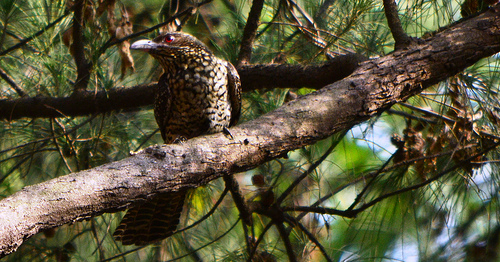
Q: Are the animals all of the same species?
A: Yes, all the animals are birds.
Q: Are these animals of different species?
A: No, all the animals are birds.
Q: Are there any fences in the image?
A: No, there are no fences.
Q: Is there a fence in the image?
A: No, there are no fences.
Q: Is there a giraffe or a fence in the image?
A: No, there are no fences or giraffes.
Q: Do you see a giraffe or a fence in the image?
A: No, there are no fences or giraffes.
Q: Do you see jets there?
A: No, there are no jets.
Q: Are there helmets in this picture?
A: No, there are no helmets.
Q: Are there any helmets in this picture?
A: No, there are no helmets.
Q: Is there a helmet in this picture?
A: No, there are no helmets.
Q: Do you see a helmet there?
A: No, there are no helmets.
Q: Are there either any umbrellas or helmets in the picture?
A: No, there are no helmets or umbrellas.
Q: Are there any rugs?
A: No, there are no rugs.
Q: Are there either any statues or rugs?
A: No, there are no rugs or statues.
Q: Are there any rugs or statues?
A: No, there are no rugs or statues.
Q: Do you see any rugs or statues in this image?
A: No, there are no rugs or statues.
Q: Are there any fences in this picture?
A: No, there are no fences.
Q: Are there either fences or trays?
A: No, there are no fences or trays.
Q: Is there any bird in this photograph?
A: Yes, there is a bird.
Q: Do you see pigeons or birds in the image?
A: Yes, there is a bird.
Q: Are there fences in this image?
A: No, there are no fences.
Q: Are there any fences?
A: No, there are no fences.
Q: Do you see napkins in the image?
A: No, there are no napkins.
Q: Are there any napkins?
A: No, there are no napkins.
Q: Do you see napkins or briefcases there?
A: No, there are no napkins or briefcases.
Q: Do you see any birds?
A: Yes, there is a bird.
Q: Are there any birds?
A: Yes, there is a bird.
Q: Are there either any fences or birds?
A: Yes, there is a bird.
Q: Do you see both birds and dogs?
A: No, there is a bird but no dogs.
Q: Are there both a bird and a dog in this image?
A: No, there is a bird but no dogs.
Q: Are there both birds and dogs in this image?
A: No, there is a bird but no dogs.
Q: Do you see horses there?
A: No, there are no horses.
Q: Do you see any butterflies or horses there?
A: No, there are no horses or butterflies.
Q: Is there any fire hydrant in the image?
A: No, there are no fire hydrants.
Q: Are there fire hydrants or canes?
A: No, there are no fire hydrants or canes.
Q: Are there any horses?
A: No, there are no horses.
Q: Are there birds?
A: Yes, there is a bird.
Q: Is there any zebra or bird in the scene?
A: Yes, there is a bird.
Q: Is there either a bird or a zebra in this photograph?
A: Yes, there is a bird.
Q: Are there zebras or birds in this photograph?
A: Yes, there is a bird.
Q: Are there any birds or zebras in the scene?
A: Yes, there is a bird.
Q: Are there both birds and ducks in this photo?
A: No, there is a bird but no ducks.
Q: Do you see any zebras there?
A: No, there are no zebras.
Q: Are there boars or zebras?
A: No, there are no zebras or boars.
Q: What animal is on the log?
A: The bird is on the log.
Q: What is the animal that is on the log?
A: The animal is a bird.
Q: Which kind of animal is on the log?
A: The animal is a bird.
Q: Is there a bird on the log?
A: Yes, there is a bird on the log.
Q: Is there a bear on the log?
A: No, there is a bird on the log.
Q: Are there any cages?
A: No, there are no cages.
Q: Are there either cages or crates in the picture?
A: No, there are no cages or crates.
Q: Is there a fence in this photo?
A: No, there are no fences.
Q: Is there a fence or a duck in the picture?
A: No, there are no fences or ducks.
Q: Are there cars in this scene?
A: No, there are no cars.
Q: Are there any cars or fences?
A: No, there are no cars or fences.